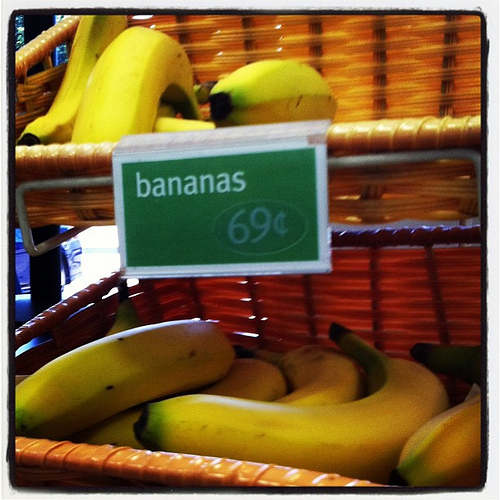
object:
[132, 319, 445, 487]
banna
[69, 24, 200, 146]
banana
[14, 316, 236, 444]
banana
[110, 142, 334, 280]
sign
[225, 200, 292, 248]
price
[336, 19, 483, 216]
basket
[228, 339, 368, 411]
bananas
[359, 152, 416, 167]
pole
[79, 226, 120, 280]
light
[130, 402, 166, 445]
end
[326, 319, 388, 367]
stem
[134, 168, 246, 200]
writing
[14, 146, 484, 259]
rack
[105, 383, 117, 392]
spot